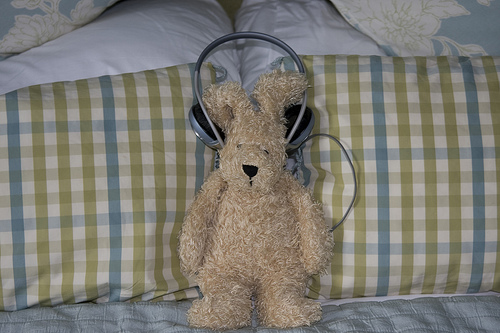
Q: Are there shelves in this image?
A: No, there are no shelves.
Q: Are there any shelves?
A: No, there are no shelves.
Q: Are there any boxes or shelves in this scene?
A: No, there are no shelves or boxes.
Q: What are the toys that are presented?
A: The toys are stuffed animals.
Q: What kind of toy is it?
A: The toys are stuffed animals.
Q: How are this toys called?
A: These are stuffed animals.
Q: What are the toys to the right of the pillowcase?
A: The toys are stuffed animals.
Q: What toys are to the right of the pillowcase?
A: The toys are stuffed animals.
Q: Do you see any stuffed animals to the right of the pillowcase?
A: Yes, there are stuffed animals to the right of the pillowcase.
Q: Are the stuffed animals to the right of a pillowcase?
A: Yes, the stuffed animals are to the right of a pillowcase.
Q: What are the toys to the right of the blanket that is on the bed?
A: The toys are stuffed animals.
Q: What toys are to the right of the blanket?
A: The toys are stuffed animals.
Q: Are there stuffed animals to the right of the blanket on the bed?
A: Yes, there are stuffed animals to the right of the blanket.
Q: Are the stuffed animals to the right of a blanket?
A: Yes, the stuffed animals are to the right of a blanket.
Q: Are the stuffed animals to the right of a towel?
A: No, the stuffed animals are to the right of a blanket.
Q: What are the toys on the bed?
A: The toys are stuffed animals.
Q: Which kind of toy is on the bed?
A: The toys are stuffed animals.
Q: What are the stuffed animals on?
A: The stuffed animals are on the bed.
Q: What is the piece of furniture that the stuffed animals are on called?
A: The piece of furniture is a bed.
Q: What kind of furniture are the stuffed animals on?
A: The stuffed animals are on the bed.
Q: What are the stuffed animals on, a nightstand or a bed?
A: The stuffed animals are on a bed.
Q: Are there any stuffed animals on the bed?
A: Yes, there are stuffed animals on the bed.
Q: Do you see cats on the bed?
A: No, there are stuffed animals on the bed.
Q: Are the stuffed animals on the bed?
A: Yes, the stuffed animals are on the bed.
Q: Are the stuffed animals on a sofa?
A: No, the stuffed animals are on the bed.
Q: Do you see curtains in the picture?
A: No, there are no curtains.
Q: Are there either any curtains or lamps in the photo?
A: No, there are no curtains or lamps.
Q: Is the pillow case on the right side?
A: No, the pillow case is on the left of the image.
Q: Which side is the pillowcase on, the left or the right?
A: The pillowcase is on the left of the image.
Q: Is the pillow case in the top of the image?
A: Yes, the pillow case is in the top of the image.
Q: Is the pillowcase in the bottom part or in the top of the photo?
A: The pillowcase is in the top of the image.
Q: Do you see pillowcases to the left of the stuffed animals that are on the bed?
A: Yes, there is a pillowcase to the left of the stuffed animals.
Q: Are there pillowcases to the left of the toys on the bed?
A: Yes, there is a pillowcase to the left of the stuffed animals.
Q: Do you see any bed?
A: Yes, there is a bed.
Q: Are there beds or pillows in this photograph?
A: Yes, there is a bed.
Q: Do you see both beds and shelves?
A: No, there is a bed but no shelves.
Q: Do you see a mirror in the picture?
A: No, there are no mirrors.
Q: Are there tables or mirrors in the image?
A: No, there are no mirrors or tables.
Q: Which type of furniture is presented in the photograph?
A: The furniture is a bed.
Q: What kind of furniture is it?
A: The piece of furniture is a bed.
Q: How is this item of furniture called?
A: This is a bed.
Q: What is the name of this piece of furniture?
A: This is a bed.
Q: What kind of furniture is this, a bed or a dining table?
A: This is a bed.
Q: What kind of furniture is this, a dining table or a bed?
A: This is a bed.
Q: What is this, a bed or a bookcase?
A: This is a bed.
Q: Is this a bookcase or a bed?
A: This is a bed.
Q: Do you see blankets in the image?
A: Yes, there is a blanket.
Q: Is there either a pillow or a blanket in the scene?
A: Yes, there is a blanket.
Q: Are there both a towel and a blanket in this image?
A: No, there is a blanket but no towels.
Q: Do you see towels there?
A: No, there are no towels.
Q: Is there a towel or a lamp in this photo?
A: No, there are no towels or lamps.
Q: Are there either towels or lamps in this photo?
A: No, there are no towels or lamps.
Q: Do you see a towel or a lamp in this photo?
A: No, there are no towels or lamps.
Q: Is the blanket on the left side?
A: Yes, the blanket is on the left of the image.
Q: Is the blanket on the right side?
A: No, the blanket is on the left of the image.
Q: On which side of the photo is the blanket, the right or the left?
A: The blanket is on the left of the image.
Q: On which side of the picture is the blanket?
A: The blanket is on the left of the image.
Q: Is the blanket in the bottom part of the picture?
A: Yes, the blanket is in the bottom of the image.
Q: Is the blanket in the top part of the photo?
A: No, the blanket is in the bottom of the image.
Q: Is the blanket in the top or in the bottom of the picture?
A: The blanket is in the bottom of the image.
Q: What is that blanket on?
A: The blanket is on the bed.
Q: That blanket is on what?
A: The blanket is on the bed.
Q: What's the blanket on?
A: The blanket is on the bed.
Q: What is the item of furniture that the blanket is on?
A: The piece of furniture is a bed.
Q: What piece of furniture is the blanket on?
A: The blanket is on the bed.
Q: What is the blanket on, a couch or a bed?
A: The blanket is on a bed.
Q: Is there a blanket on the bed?
A: Yes, there is a blanket on the bed.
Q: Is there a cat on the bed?
A: No, there is a blanket on the bed.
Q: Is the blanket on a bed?
A: Yes, the blanket is on a bed.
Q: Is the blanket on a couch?
A: No, the blanket is on a bed.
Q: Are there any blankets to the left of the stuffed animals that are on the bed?
A: Yes, there is a blanket to the left of the stuffed animals.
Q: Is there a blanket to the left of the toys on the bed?
A: Yes, there is a blanket to the left of the stuffed animals.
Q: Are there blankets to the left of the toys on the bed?
A: Yes, there is a blanket to the left of the stuffed animals.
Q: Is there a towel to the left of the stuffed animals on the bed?
A: No, there is a blanket to the left of the stuffed animals.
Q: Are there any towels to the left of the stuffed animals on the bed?
A: No, there is a blanket to the left of the stuffed animals.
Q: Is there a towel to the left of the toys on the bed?
A: No, there is a blanket to the left of the stuffed animals.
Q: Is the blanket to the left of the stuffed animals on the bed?
A: Yes, the blanket is to the left of the stuffed animals.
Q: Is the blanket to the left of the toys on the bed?
A: Yes, the blanket is to the left of the stuffed animals.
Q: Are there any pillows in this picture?
A: Yes, there are pillows.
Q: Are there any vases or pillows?
A: Yes, there are pillows.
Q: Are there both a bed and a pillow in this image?
A: Yes, there are both a pillow and a bed.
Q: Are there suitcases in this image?
A: No, there are no suitcases.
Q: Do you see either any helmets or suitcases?
A: No, there are no suitcases or helmets.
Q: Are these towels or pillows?
A: These are pillows.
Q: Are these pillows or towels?
A: These are pillows.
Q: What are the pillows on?
A: The pillows are on the bed.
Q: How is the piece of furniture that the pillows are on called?
A: The piece of furniture is a bed.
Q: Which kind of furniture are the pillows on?
A: The pillows are on the bed.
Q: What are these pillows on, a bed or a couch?
A: The pillows are on a bed.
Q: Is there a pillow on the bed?
A: Yes, there are pillows on the bed.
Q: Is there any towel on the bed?
A: No, there are pillows on the bed.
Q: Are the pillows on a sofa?
A: No, the pillows are on a bed.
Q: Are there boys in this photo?
A: No, there are no boys.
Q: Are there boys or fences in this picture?
A: No, there are no boys or fences.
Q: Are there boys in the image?
A: No, there are no boys.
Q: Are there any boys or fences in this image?
A: No, there are no boys or fences.